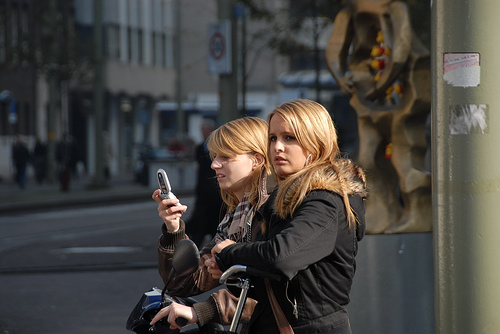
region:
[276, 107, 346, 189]
the silver is brown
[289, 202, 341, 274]
the jacket is black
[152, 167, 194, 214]
the phone is silver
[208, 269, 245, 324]
the metal bar is silver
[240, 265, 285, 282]
the handle is black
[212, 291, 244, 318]
the jacket is brown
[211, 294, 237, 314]
the jacket is leather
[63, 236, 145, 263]
the manhole cover is on the road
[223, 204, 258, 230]
the scarf is blue and white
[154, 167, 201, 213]
the phone is a flipflop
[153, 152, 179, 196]
A flip-open cellphone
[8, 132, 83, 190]
Three people standing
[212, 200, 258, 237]
A black stripe scarf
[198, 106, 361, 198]
Two blonde ladies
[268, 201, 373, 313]
A black coat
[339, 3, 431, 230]
A sculpture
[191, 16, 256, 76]
A traffic sign in the square shape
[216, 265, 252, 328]
The holder of an umbrella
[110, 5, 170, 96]
Windows of a building in the back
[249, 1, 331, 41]
Tree leaves in the back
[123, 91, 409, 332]
Two Women out in the street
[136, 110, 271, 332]
Woman is on her cell phone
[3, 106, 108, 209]
People are blurred in the left of background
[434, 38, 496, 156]
Old torn on stickers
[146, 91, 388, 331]
Women have blond hair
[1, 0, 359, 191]
Background is blurry and out of focus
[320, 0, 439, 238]
Metal Figure is in the background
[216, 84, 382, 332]
Woman is wearing a black hooded coat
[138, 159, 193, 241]
Woman has a grey flip phone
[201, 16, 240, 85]
White Sign on wooden street pole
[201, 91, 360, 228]
both girls have strawberry blond hair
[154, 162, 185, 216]
the girl is holding a silver cell phone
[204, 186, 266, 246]
the girl is wearing a plaid scarf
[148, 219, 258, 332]
the girl is wearing a brown jacket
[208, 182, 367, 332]
the girl has on a black jacket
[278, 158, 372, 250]
the black jacket has a hood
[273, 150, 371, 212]
the hood on the black jacket has fur trim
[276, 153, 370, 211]
the fur trim on the black jacket is brown tan and black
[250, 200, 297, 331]
the girl has a brown leather strap across her body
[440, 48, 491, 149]
two stickers have been pealed off of the post behind the girls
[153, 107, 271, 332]
woman looking at her cell phone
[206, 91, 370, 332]
woman looking down the street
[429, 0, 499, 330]
grey metal post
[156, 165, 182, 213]
grey flip style cell phone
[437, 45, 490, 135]
peeling sticker on pole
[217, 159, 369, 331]
black fur trimmed jacket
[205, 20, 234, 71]
white sign on post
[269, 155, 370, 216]
fur lining of a jacket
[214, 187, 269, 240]
fabric of a plaid patterned shirt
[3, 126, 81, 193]
people walking on the sidewalk